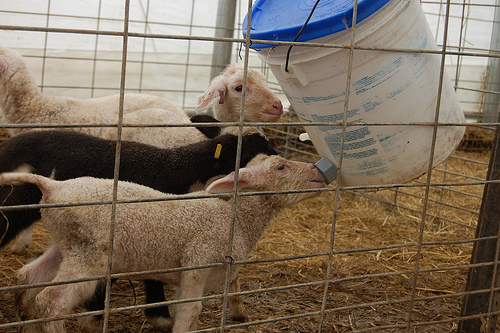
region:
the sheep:
[68, 60, 327, 260]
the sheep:
[131, 156, 279, 301]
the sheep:
[117, 102, 319, 327]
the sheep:
[120, 117, 225, 299]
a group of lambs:
[1, 35, 303, 328]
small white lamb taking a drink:
[16, 113, 401, 330]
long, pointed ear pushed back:
[206, 168, 266, 198]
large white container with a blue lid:
[225, 5, 499, 207]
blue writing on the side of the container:
[308, 110, 381, 169]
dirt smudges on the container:
[386, 143, 456, 183]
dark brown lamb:
[3, 118, 273, 327]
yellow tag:
[210, 140, 225, 162]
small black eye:
[276, 161, 282, 170]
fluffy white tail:
[0, 168, 50, 192]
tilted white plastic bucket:
[234, 4, 481, 194]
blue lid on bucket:
[231, 5, 373, 54]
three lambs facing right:
[16, 68, 297, 309]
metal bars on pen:
[305, 160, 355, 246]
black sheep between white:
[40, 126, 261, 202]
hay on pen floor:
[275, 221, 382, 293]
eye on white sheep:
[227, 76, 242, 93]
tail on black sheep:
[10, 165, 70, 196]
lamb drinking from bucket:
[299, 155, 341, 195]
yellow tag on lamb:
[204, 136, 229, 166]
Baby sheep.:
[2, 45, 327, 319]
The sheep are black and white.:
[3, 46, 331, 331]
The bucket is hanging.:
[238, 1, 475, 188]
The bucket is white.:
[245, 0, 482, 197]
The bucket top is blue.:
[241, 2, 430, 51]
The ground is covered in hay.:
[306, 222, 438, 292]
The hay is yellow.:
[286, 212, 394, 254]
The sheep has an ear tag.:
[199, 137, 230, 167]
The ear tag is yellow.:
[206, 132, 232, 169]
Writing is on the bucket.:
[305, 52, 425, 185]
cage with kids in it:
[1, 1, 498, 330]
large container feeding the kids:
[240, 0, 465, 192]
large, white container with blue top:
[240, 0, 465, 187]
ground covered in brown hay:
[0, 127, 497, 329]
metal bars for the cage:
[0, 1, 498, 330]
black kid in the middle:
[2, 126, 279, 328]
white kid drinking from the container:
[3, 155, 324, 330]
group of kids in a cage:
[0, 47, 318, 332]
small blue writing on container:
[286, 37, 437, 176]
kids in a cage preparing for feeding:
[0, 45, 325, 331]